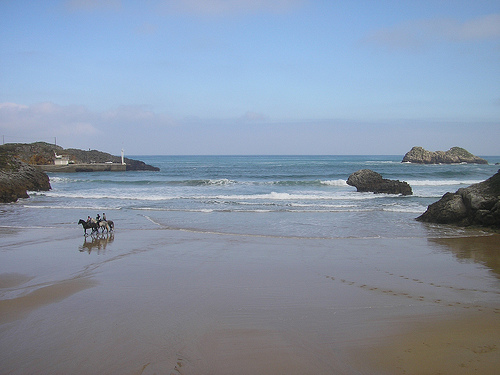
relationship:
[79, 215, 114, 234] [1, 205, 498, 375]
horseback riders on shore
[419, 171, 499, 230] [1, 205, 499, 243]
rock on shore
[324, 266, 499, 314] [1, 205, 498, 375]
tracks are in shore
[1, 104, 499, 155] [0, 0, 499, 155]
clouds are in sky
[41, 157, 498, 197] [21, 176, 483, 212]
ocean with waves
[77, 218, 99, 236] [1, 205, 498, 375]
black horse on shore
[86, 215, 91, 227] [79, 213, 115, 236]
horseback riders riding horses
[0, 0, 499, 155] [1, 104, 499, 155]
sky has clouds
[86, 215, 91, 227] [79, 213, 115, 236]
horseback riders are riding horses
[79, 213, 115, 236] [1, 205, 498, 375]
horses are on shore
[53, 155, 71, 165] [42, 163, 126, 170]
house on beach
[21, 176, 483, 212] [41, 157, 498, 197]
waves in ocean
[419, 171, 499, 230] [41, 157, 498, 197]
rock in ocean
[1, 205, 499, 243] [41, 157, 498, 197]
shore of ocean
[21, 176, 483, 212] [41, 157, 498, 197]
waves of ocean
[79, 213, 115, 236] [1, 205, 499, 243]
horses on shore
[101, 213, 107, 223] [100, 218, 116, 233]
person on horses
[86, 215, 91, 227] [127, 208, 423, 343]
horseback riders on beach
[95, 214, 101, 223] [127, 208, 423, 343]
person on beach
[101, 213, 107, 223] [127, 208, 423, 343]
person on beach